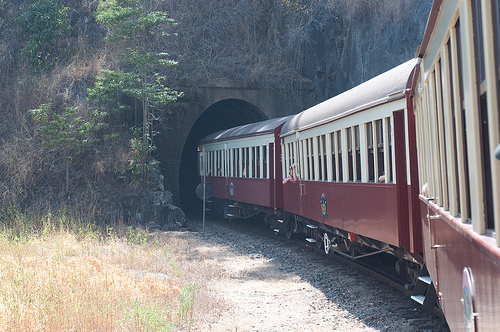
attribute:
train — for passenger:
[194, 94, 433, 276]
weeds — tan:
[36, 212, 207, 325]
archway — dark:
[149, 93, 252, 221]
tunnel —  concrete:
[161, 87, 304, 226]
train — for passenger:
[158, 88, 487, 273]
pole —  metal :
[180, 138, 247, 262]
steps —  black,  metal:
[409, 261, 438, 311]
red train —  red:
[197, 0, 499, 330]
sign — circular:
[285, 177, 343, 234]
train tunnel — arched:
[171, 87, 278, 237]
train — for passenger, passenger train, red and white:
[191, 0, 496, 328]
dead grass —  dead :
[68, 256, 140, 307]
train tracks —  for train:
[319, 225, 427, 312]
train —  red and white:
[194, 66, 419, 257]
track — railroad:
[206, 220, 446, 325]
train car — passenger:
[201, 122, 296, 225]